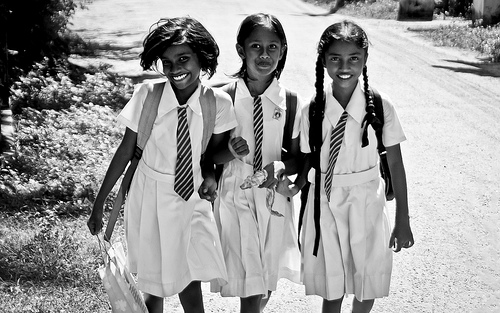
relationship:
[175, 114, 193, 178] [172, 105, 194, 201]
stripe on tie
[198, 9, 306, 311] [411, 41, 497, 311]
person walking on a street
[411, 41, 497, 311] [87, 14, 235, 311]
street behind person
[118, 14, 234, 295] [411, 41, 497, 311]
person on street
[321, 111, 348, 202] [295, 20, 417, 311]
tie worn by child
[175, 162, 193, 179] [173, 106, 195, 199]
stripe on tie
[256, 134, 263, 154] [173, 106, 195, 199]
stripe on tie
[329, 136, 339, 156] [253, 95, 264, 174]
stripe on tie